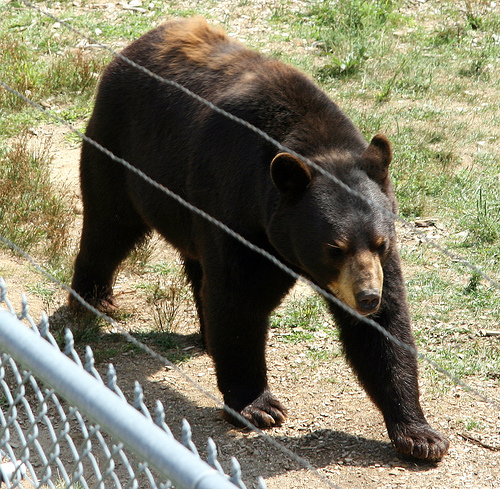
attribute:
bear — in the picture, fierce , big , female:
[32, 20, 447, 467]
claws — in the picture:
[396, 434, 452, 456]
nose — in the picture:
[358, 286, 385, 309]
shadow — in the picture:
[0, 306, 312, 481]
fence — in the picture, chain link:
[1, 288, 264, 483]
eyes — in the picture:
[321, 232, 405, 259]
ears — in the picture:
[260, 128, 394, 176]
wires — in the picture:
[12, 12, 495, 404]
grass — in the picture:
[280, 296, 329, 343]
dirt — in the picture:
[78, 319, 212, 414]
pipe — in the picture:
[1, 312, 247, 486]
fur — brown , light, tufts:
[159, 12, 215, 63]